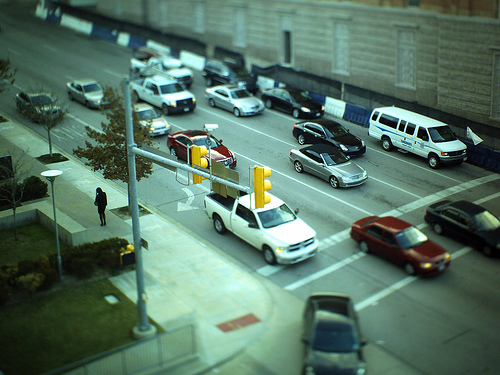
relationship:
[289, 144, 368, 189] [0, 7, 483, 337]
car on road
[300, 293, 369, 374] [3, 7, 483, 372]
car on road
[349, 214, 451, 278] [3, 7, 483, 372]
car on road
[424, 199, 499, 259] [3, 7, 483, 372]
car on road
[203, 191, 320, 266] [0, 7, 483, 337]
car on road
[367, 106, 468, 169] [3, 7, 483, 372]
van on road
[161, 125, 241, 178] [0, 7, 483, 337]
vehicle on road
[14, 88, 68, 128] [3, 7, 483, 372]
vehicle on road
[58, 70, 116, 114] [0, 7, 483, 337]
vehicle on road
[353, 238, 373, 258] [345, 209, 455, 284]
tire of car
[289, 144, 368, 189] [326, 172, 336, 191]
car has tire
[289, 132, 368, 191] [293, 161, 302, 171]
car has tire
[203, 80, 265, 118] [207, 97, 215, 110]
car has tire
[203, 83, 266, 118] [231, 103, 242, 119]
car has tire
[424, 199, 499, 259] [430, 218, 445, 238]
car has tire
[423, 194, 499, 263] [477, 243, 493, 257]
car has tire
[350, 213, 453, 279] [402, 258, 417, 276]
car has tire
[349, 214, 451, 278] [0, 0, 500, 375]
car on road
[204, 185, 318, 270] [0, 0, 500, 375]
car on road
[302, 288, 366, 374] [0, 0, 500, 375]
car on road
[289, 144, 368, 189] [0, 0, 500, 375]
car on road